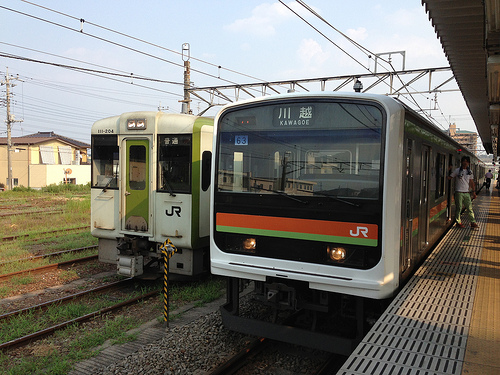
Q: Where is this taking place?
A: Train station.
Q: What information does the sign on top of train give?
A: Destination.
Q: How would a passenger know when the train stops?
A: Timetable.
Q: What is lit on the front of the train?
A: Headlights.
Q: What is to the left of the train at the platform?
A: Another train.